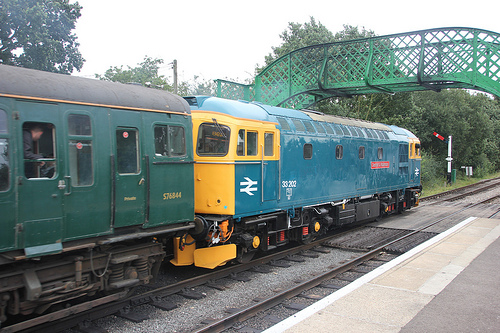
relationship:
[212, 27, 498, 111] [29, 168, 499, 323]
bridge above railroad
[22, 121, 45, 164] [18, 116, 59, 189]
man in window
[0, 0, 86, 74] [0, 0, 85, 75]
tree has leaves